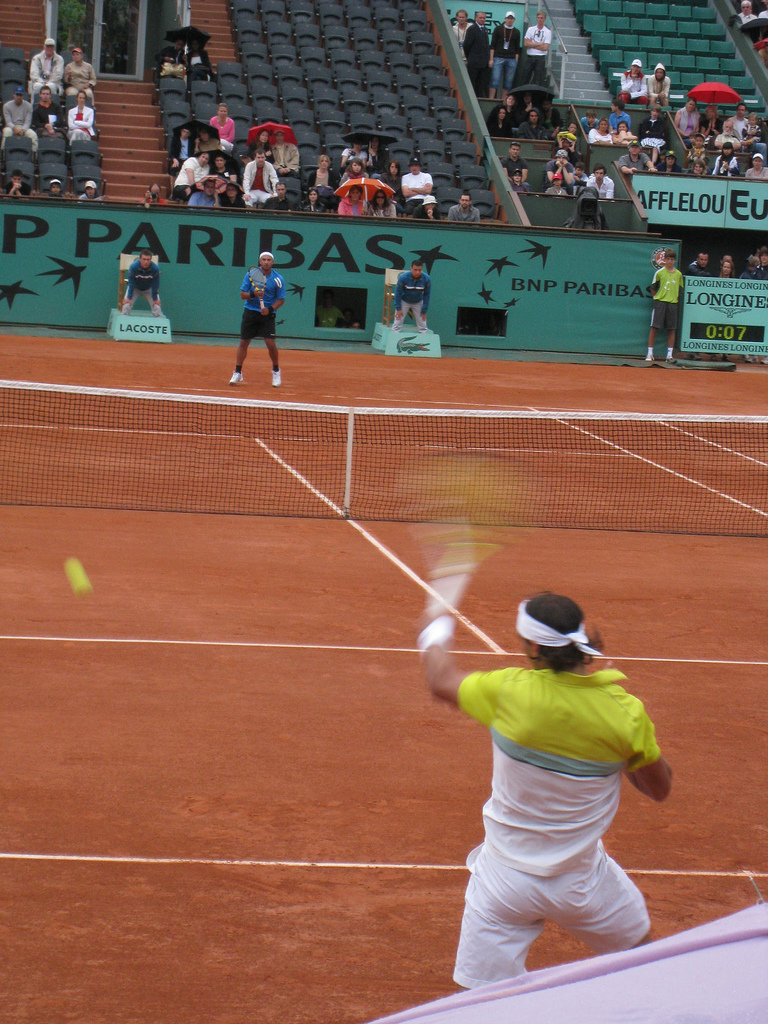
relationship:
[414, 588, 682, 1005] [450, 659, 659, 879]
player in shirt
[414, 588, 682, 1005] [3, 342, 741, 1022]
player on tennis court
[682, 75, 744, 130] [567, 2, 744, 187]
umbrella in stands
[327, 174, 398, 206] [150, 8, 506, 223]
umbrella in stands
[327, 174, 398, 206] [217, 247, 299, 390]
umbrella behind player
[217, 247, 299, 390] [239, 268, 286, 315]
player in shirt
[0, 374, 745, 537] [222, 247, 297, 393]
tennis net separating player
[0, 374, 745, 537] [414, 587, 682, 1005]
tennis net separating player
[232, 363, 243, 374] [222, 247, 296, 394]
sock on player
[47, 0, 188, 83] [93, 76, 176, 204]
door above stairs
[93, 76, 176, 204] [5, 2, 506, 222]
stairs in stands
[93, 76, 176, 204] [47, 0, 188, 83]
stairs leading to door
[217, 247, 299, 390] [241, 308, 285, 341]
player in shorts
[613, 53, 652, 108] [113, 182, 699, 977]
person watch tennis match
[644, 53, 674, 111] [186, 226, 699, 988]
person watch tennis match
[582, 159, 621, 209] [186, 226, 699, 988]
person watch tennis match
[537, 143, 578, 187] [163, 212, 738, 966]
person watch tennis match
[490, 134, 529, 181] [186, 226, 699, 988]
person watch tennis match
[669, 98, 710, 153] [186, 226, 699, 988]
person watch tennis match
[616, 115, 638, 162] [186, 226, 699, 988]
person watch tennis match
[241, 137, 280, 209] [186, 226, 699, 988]
person watch tennis match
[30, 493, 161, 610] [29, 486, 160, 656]
air in air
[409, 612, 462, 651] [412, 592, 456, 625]
wrist band on hand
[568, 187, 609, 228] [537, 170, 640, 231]
camera on stands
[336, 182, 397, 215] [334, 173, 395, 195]
spectators under umbrella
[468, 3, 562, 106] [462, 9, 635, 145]
people in stands